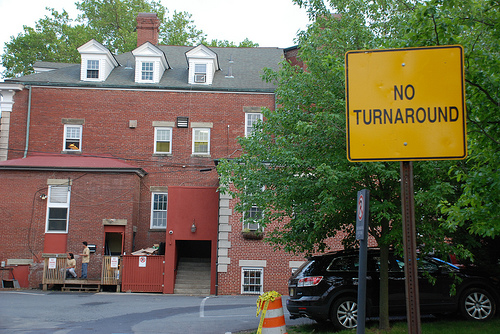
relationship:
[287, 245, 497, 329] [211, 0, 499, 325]
car parked under tree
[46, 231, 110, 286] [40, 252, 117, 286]
people sitting on patio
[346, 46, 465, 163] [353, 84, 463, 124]
sign says "no turnaround"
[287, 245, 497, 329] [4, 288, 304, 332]
car parked in lot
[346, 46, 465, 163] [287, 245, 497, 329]
sign next to car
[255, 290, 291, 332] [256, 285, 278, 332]
cone with caution tape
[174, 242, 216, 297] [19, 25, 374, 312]
stairway into building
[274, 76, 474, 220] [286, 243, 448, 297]
tree next to vehicle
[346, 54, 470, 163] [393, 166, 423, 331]
sign on post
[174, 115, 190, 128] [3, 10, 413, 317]
light on building